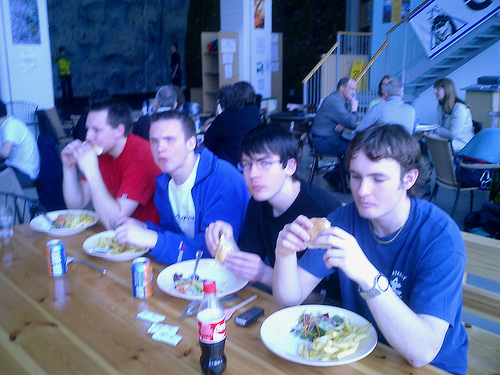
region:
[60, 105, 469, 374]
four guys eating lunch at a table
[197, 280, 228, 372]
a plastic bottle of Coke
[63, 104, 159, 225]
college student with the red t-shirt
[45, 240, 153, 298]
two aluminum cans of soda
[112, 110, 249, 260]
guy in the white shirt and blue jacket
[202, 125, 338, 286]
guy with the black t-shirt and glasses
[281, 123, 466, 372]
guy on the right with the blue t-shirt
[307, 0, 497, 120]
stairs in the backgound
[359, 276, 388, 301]
silver wristwatch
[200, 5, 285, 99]
white column with brown shelving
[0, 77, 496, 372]
people sitting at tables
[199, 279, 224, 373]
bottle with red cap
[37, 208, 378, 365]
row of white bowls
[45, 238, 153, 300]
two cans on table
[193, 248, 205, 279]
handle of metal utensil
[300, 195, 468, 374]
blue short sleeved shirt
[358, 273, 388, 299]
watch on man's wrist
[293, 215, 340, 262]
bread being held by fingers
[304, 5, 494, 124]
railing on side of stairwell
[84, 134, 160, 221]
red shirt on man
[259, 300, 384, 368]
A round white plate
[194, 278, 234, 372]
A plastic soda bottle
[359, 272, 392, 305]
A watch on a man's wrist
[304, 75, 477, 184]
Four people sitting at a table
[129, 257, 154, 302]
An aluminum can on the table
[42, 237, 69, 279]
An orange and blue aluminum can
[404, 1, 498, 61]
A banner hanging on the stairway rail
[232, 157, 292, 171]
Glasses on a man's face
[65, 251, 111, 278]
A silver utensil on the table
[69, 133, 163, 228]
A red shirt on a man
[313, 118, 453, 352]
this is a man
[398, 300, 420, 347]
the man is light skinned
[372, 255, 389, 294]
this is a watch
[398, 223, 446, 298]
this is a t shirt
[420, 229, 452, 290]
the shirt is blue in color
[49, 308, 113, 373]
this is a table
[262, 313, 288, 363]
this is a plate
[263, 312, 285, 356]
the plate is white in color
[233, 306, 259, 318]
this is a phone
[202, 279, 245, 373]
this is a bottle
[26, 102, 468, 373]
Four men sitting at a table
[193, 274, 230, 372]
Plastic bottle of Coca-Cola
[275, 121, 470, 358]
Man eating a sandwich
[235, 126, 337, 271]
Man wearing glasses and black shirt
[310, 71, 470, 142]
People seated at table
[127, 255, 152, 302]
Soda can on table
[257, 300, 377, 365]
Plate of food on table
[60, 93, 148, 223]
Man biting into sandwich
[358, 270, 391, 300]
Watch on man's left wrist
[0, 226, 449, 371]
Wooden tabletop